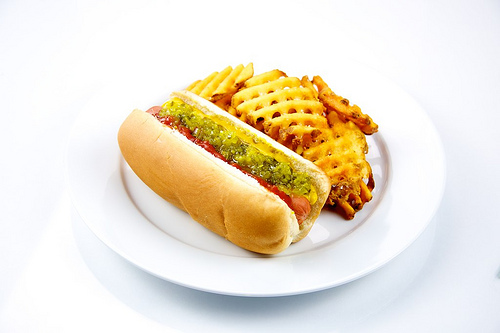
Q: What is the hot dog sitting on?
A: A plate.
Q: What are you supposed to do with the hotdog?
A: Eat it.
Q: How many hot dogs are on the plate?
A: One.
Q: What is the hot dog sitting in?
A: A bun.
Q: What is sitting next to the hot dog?
A: Waffle fries.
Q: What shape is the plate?
A: Circular.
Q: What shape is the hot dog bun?
A: Long.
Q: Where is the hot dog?
A: In the bun covered with sauces.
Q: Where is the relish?
A: On hotdog.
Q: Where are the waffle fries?
A: On the plate.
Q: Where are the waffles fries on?
A: The plate.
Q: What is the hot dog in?
A: Hot dog bun.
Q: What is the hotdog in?
A: A bun.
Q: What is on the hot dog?
A: Ketchup, mustard and relish.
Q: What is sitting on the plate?
A: A hot dog and waffle fries.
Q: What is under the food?
A: A white plate.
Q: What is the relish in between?
A: Ketchup and mustard.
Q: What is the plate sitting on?
A: A white surface.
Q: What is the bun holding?
A: A hotdog.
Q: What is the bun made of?
A: Flour.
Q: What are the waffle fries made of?
A: Potatoes.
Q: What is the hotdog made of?
A: Pork.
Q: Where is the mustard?
A: On the hot dog.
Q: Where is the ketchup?
A: On a hot dog.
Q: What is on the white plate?
A: Food.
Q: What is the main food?
A: Hotdog.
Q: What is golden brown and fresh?
A: Fries.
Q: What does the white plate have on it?
A: Food.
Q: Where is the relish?
A: On the hotdog.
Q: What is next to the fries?
A: A hotdog.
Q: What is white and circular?
A: A plate.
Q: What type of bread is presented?
A: White bread.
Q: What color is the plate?
A: White.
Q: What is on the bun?
A: The hot dog.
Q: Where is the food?
A: The plate.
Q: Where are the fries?
A: Right side.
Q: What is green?
A: The relish.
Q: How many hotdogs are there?
A: One.